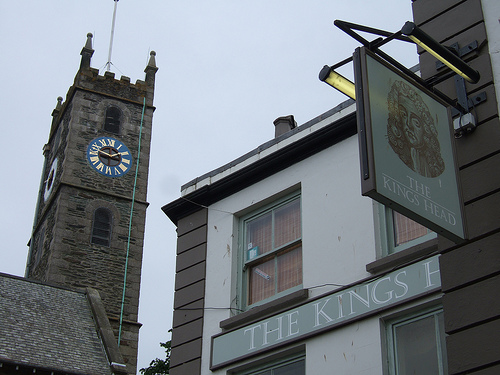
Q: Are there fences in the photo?
A: No, there are no fences.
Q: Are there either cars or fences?
A: No, there are no fences or cars.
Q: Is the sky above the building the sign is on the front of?
A: Yes, the sky is above the building.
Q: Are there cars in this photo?
A: No, there are no cars.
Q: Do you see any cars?
A: No, there are no cars.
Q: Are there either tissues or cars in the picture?
A: No, there are no cars or tissues.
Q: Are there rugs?
A: No, there are no rugs.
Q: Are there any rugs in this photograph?
A: No, there are no rugs.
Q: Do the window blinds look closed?
A: Yes, the blinds are closed.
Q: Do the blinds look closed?
A: Yes, the blinds are closed.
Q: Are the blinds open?
A: No, the blinds are closed.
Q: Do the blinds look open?
A: No, the blinds are closed.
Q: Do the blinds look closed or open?
A: The blinds are closed.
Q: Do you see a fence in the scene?
A: No, there are no fences.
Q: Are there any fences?
A: No, there are no fences.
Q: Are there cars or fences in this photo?
A: No, there are no fences or cars.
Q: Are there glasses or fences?
A: No, there are no fences or glasses.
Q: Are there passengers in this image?
A: No, there are no passengers.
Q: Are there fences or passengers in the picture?
A: No, there are no passengers or fences.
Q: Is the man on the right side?
A: Yes, the man is on the right of the image.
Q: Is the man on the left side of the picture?
A: No, the man is on the right of the image.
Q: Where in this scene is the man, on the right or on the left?
A: The man is on the right of the image.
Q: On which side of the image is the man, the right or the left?
A: The man is on the right of the image.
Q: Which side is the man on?
A: The man is on the right of the image.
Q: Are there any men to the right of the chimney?
A: Yes, there is a man to the right of the chimney.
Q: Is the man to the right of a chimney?
A: Yes, the man is to the right of a chimney.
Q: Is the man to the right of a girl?
A: No, the man is to the right of a chimney.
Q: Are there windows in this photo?
A: Yes, there is a window.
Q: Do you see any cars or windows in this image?
A: Yes, there is a window.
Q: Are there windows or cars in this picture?
A: Yes, there is a window.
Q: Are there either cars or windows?
A: Yes, there is a window.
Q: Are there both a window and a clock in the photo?
A: Yes, there are both a window and a clock.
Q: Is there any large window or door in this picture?
A: Yes, there is a large window.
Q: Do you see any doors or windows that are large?
A: Yes, the window is large.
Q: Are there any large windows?
A: Yes, there is a large window.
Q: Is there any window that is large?
A: Yes, there is a window that is large.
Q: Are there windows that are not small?
A: Yes, there is a large window.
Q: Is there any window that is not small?
A: Yes, there is a large window.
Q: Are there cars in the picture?
A: No, there are no cars.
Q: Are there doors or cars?
A: No, there are no cars or doors.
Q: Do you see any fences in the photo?
A: No, there are no fences.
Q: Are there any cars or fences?
A: No, there are no fences or cars.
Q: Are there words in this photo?
A: Yes, there are words.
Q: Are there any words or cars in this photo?
A: Yes, there are words.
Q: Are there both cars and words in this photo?
A: No, there are words but no cars.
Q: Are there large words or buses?
A: Yes, there are large words.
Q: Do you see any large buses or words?
A: Yes, there are large words.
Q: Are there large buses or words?
A: Yes, there are large words.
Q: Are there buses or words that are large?
A: Yes, the words are large.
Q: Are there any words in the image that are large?
A: Yes, there are words that are large.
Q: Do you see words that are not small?
A: Yes, there are large words.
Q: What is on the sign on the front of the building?
A: The words are on the sign.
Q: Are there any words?
A: Yes, there are words.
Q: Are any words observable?
A: Yes, there are words.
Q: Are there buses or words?
A: Yes, there are words.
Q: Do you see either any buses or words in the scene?
A: Yes, there are words.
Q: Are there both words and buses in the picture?
A: No, there are words but no buses.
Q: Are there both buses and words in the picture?
A: No, there are words but no buses.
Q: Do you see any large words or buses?
A: Yes, there are large words.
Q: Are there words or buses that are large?
A: Yes, the words are large.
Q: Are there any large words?
A: Yes, there are large words.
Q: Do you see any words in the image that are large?
A: Yes, there are words that are large.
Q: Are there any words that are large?
A: Yes, there are words that are large.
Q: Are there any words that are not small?
A: Yes, there are large words.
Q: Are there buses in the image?
A: No, there are no buses.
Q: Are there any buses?
A: No, there are no buses.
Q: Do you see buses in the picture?
A: No, there are no buses.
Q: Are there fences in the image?
A: No, there are no fences.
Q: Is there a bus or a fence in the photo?
A: No, there are no fences or buses.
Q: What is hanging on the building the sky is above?
A: The sign is hanging on the building.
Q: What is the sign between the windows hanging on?
A: The sign is hanging on the building.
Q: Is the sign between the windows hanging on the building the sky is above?
A: Yes, the sign is hanging on the building.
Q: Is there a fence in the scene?
A: No, there are no fences.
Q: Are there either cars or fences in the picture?
A: No, there are no fences or cars.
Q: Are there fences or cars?
A: No, there are no fences or cars.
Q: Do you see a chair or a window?
A: Yes, there is a window.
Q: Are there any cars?
A: No, there are no cars.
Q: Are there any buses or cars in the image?
A: No, there are no cars or buses.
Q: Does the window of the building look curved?
A: Yes, the window is curved.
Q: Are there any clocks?
A: Yes, there is a clock.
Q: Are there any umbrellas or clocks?
A: Yes, there is a clock.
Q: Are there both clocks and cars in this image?
A: No, there is a clock but no cars.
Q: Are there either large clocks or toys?
A: Yes, there is a large clock.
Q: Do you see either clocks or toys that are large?
A: Yes, the clock is large.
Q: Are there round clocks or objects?
A: Yes, there is a round clock.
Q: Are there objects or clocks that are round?
A: Yes, the clock is round.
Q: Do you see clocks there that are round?
A: Yes, there is a round clock.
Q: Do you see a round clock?
A: Yes, there is a round clock.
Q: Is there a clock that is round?
A: Yes, there is a clock that is round.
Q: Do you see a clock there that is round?
A: Yes, there is a clock that is round.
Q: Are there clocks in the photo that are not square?
A: Yes, there is a round clock.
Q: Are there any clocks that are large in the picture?
A: Yes, there is a large clock.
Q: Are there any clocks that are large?
A: Yes, there is a clock that is large.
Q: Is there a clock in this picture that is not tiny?
A: Yes, there is a large clock.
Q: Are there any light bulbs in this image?
A: No, there are no light bulbs.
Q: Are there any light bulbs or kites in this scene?
A: No, there are no light bulbs or kites.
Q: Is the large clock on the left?
A: Yes, the clock is on the left of the image.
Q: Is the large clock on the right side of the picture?
A: No, the clock is on the left of the image.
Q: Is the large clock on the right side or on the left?
A: The clock is on the left of the image.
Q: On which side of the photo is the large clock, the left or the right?
A: The clock is on the left of the image.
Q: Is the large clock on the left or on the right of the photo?
A: The clock is on the left of the image.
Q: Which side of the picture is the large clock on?
A: The clock is on the left of the image.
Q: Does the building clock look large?
A: Yes, the clock is large.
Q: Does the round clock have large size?
A: Yes, the clock is large.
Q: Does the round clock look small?
A: No, the clock is large.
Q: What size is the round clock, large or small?
A: The clock is large.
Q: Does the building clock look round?
A: Yes, the clock is round.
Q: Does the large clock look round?
A: Yes, the clock is round.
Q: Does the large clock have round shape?
A: Yes, the clock is round.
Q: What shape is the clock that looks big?
A: The clock is round.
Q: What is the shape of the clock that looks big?
A: The clock is round.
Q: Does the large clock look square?
A: No, the clock is round.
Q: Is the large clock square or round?
A: The clock is round.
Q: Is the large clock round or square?
A: The clock is round.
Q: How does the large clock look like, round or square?
A: The clock is round.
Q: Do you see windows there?
A: Yes, there are windows.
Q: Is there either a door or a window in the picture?
A: Yes, there are windows.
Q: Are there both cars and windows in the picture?
A: No, there are windows but no cars.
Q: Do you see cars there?
A: No, there are no cars.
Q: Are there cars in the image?
A: No, there are no cars.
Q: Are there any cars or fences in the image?
A: No, there are no cars or fences.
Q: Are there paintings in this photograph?
A: No, there are no paintings.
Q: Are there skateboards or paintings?
A: No, there are no paintings or skateboards.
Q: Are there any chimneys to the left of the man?
A: Yes, there is a chimney to the left of the man.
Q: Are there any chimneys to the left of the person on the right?
A: Yes, there is a chimney to the left of the man.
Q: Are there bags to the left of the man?
A: No, there is a chimney to the left of the man.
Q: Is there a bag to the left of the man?
A: No, there is a chimney to the left of the man.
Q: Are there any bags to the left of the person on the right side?
A: No, there is a chimney to the left of the man.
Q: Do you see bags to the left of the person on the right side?
A: No, there is a chimney to the left of the man.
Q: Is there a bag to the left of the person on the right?
A: No, there is a chimney to the left of the man.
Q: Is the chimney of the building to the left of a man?
A: Yes, the chimney is to the left of a man.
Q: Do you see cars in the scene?
A: No, there are no cars.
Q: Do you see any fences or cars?
A: No, there are no cars or fences.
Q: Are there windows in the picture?
A: Yes, there is a window.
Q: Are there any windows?
A: Yes, there is a window.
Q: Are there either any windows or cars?
A: Yes, there is a window.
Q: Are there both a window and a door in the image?
A: No, there is a window but no doors.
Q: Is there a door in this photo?
A: No, there are no doors.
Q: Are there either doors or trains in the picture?
A: No, there are no doors or trains.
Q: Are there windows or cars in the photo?
A: Yes, there is a window.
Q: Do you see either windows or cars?
A: Yes, there is a window.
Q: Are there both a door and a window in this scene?
A: No, there is a window but no doors.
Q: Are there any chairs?
A: No, there are no chairs.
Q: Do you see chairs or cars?
A: No, there are no chairs or cars.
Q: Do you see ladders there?
A: No, there are no ladders.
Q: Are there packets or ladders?
A: No, there are no ladders or packets.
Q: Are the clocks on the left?
A: Yes, the clocks are on the left of the image.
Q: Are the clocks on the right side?
A: No, the clocks are on the left of the image.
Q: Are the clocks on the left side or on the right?
A: The clocks are on the left of the image.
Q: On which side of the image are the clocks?
A: The clocks are on the left of the image.